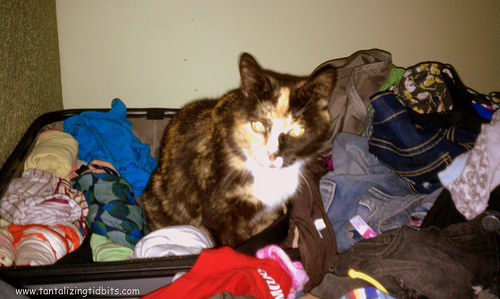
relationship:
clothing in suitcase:
[62, 106, 139, 181] [25, 103, 303, 293]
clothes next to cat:
[322, 46, 498, 249] [156, 58, 349, 281]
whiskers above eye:
[204, 135, 253, 187] [244, 117, 271, 135]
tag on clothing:
[348, 210, 386, 250] [360, 110, 402, 176]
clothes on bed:
[322, 46, 498, 247] [0, 94, 497, 297]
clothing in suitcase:
[0, 101, 159, 267] [0, 107, 291, 297]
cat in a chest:
[152, 51, 345, 255] [0, 102, 315, 278]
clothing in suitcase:
[0, 110, 151, 260] [3, 267, 194, 294]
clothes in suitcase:
[322, 46, 498, 249] [3, 267, 194, 294]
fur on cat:
[172, 126, 202, 170] [197, 69, 317, 229]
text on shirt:
[257, 266, 284, 297] [137, 243, 293, 297]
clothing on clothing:
[360, 94, 469, 185] [362, 70, 497, 231]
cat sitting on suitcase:
[152, 51, 345, 255] [3, 106, 312, 291]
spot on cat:
[243, 154, 307, 216] [152, 51, 345, 255]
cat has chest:
[152, 51, 345, 255] [218, 146, 316, 248]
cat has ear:
[152, 51, 345, 255] [302, 60, 342, 95]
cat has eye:
[164, 70, 352, 255] [159, 107, 304, 243]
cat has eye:
[152, 51, 345, 255] [288, 124, 308, 140]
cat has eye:
[152, 51, 345, 255] [248, 117, 270, 137]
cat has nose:
[152, 51, 345, 255] [264, 140, 283, 161]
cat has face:
[152, 51, 345, 255] [240, 73, 313, 158]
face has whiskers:
[240, 73, 313, 158] [204, 135, 253, 174]